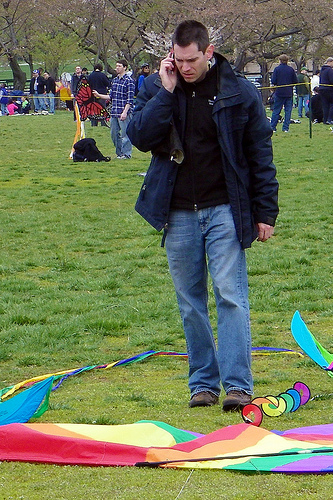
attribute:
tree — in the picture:
[116, 0, 331, 95]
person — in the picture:
[126, 18, 279, 410]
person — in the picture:
[264, 53, 301, 133]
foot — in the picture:
[178, 378, 223, 407]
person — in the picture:
[69, 63, 87, 92]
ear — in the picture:
[202, 42, 217, 61]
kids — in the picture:
[4, 92, 30, 112]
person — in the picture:
[80, 62, 174, 131]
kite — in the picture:
[0, 411, 330, 474]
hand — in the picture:
[257, 223, 274, 242]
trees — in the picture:
[1, 1, 332, 106]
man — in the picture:
[125, 20, 278, 409]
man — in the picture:
[91, 56, 138, 160]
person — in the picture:
[30, 59, 87, 116]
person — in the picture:
[113, 2, 299, 421]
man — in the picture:
[129, 41, 332, 326]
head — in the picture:
[168, 19, 209, 85]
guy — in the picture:
[110, 13, 299, 418]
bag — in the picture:
[73, 136, 109, 161]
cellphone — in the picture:
[157, 46, 182, 77]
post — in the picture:
[308, 78, 315, 138]